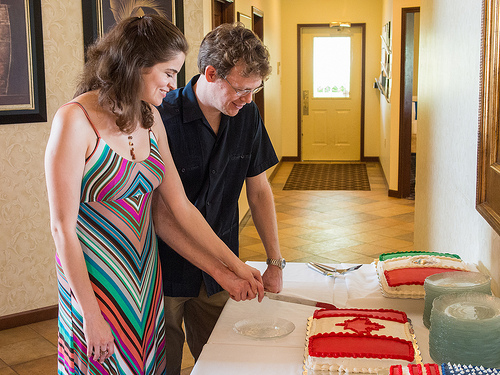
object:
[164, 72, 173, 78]
eye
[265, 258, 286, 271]
watch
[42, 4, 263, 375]
woman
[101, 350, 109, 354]
ring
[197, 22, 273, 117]
head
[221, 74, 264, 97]
glasses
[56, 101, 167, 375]
dress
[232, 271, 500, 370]
plate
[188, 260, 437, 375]
cloth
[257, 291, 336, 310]
knife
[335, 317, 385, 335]
leaf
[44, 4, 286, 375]
couple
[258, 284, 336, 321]
serving piece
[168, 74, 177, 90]
nose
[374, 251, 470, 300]
cake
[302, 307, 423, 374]
cake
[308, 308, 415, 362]
canada flag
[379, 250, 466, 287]
frosting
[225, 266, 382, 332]
cutting cake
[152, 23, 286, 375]
man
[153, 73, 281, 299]
shirt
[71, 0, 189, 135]
hair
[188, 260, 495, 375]
table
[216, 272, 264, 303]
hand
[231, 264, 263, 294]
hand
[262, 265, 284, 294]
hand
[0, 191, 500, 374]
floor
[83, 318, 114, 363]
hand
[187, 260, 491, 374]
tablecloth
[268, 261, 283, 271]
wrist